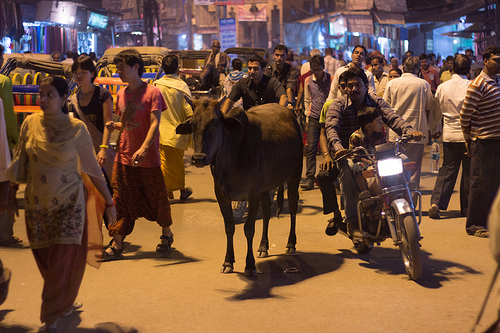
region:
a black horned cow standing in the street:
[171, 86, 311, 290]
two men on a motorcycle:
[313, 66, 433, 290]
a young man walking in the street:
[101, 46, 179, 261]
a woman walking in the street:
[11, 74, 123, 332]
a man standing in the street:
[465, 47, 496, 239]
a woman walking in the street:
[152, 52, 199, 201]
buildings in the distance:
[4, 1, 493, 52]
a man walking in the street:
[300, 51, 330, 188]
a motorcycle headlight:
[366, 154, 408, 184]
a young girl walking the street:
[64, 51, 109, 251]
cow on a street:
[148, 76, 338, 296]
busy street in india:
[6, 3, 497, 324]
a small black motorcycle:
[311, 122, 468, 277]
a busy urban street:
[2, 4, 492, 326]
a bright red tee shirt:
[93, 81, 172, 184]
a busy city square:
[5, 7, 490, 327]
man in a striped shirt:
[449, 40, 499, 247]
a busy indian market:
[3, 2, 496, 327]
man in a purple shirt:
[298, 49, 340, 194]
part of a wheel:
[383, 205, 438, 281]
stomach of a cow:
[271, 140, 298, 182]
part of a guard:
[388, 192, 413, 226]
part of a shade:
[296, 252, 326, 275]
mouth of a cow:
[185, 159, 215, 193]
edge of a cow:
[283, 259, 317, 289]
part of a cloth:
[41, 258, 83, 301]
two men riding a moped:
[322, 70, 439, 266]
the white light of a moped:
[374, 147, 414, 183]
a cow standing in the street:
[176, 95, 313, 279]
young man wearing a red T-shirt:
[111, 84, 173, 171]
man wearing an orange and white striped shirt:
[460, 74, 499, 143]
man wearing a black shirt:
[238, 61, 285, 104]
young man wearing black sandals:
[93, 229, 181, 265]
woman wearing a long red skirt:
[19, 212, 101, 322]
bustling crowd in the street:
[368, 37, 499, 96]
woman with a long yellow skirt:
[159, 134, 194, 196]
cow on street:
[167, 83, 302, 283]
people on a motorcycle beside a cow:
[185, 65, 430, 288]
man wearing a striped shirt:
[456, 48, 493, 144]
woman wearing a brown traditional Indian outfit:
[0, 65, 120, 327]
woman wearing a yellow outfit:
[150, 46, 195, 197]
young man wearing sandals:
[90, 35, 175, 261]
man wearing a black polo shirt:
[216, 55, 292, 120]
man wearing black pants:
[420, 127, 470, 222]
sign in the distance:
[211, 11, 237, 61]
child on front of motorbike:
[332, 100, 416, 217]